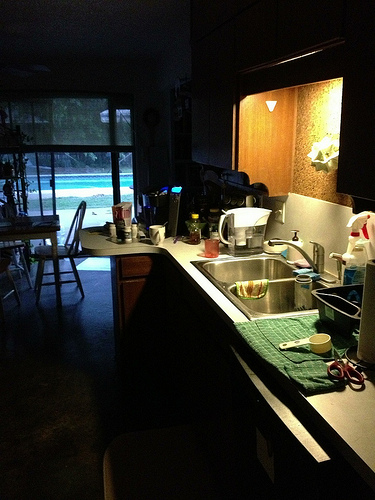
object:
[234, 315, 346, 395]
dish towel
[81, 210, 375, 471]
counter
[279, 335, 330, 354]
measuring cup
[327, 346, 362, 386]
scissors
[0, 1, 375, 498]
kitchen area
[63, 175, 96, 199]
pool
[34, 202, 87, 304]
chair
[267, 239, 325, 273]
faucet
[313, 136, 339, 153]
light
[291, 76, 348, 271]
wall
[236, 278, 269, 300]
rag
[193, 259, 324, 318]
sink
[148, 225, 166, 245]
cup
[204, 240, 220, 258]
cup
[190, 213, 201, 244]
bottle of honey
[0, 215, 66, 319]
table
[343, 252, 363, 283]
dish detergent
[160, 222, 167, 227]
spoon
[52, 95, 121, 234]
sliding door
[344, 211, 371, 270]
spray bottle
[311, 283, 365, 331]
dish drainer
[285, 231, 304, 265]
soap dispenser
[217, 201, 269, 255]
pitcher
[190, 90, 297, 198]
cabinet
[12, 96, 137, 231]
backyard